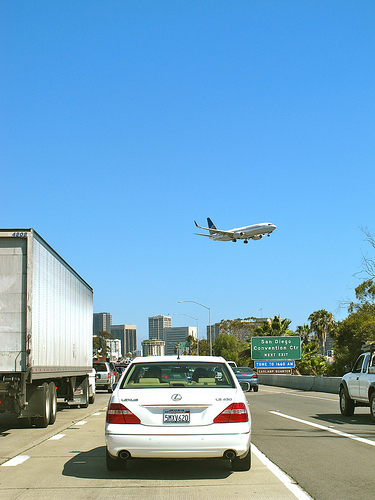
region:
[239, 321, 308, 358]
Sign for San Diego Convention Center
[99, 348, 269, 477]
white Lexus on the highway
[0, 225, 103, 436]
white tractor trailer truck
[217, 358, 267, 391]
blue car on the road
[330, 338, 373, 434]
white pickup truck driving down the street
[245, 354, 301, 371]
blue and white street sign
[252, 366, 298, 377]
brown and white street sign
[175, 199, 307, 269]
airplane in the sky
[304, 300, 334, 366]
tall green palm tree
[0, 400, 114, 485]
white dotted line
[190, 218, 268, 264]
white airplane is flying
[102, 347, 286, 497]
white luxury car on road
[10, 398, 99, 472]
white hash marks on road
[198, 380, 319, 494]
white line to right of car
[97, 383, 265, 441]
red taillights on car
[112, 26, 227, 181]
sky is blue and cloudless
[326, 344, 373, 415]
white truck to right of car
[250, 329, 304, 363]
green and white road sign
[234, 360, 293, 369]
blue and white road sign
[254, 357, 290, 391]
brown and white road sign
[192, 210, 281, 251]
airplane flying in the sky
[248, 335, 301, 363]
green street sign with san diego convention ctr next right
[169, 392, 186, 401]
vehicle emblem which shows lexus symbol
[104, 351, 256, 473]
white passenger vehicle with lexus symbol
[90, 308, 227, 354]
city skyline with five buildings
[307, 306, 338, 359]
GREEN PALM TREE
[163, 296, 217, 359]
TWO STREET LIGHTS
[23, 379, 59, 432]
PAIR OF TRUCK TIRES WITH WHITE RIMS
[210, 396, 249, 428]
RED REAR STOP LIGHTS WITH WHITE IN THE MIDDLE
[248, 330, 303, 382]
THREE STREET SIGNS STACKED GREEN BLUE BROWN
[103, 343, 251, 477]
white car on the road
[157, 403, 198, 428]
license plate on the car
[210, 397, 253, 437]
tail light on the car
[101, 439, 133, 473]
tire on the car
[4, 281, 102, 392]
semi truck on the highway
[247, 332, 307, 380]
sign next to the highway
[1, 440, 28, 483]
white line on the highway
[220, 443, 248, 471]
exhaust on the white car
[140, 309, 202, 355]
buildings in the distance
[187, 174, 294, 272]
an airplane in the air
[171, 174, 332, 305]
an airplane in the sky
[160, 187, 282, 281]
a plane in the air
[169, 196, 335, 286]
a plane in the sky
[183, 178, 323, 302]
an airiplane flying in the sky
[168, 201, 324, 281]
a plane flying in the sky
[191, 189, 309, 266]
an airplane that is flying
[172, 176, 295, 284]
a plane that is flying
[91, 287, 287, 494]
a white car in font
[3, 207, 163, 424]
an 18 wheeler on the road